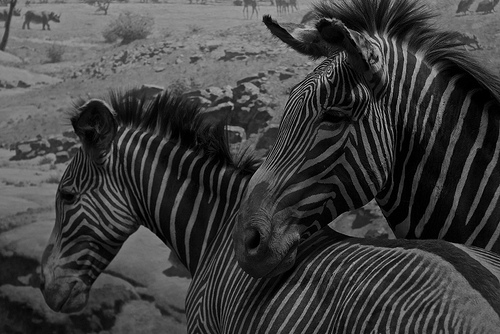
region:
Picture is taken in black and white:
[4, 8, 483, 324]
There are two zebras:
[44, 13, 492, 330]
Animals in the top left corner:
[1, 0, 71, 34]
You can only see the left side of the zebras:
[27, 9, 491, 328]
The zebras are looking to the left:
[37, 68, 385, 290]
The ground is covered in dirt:
[3, 47, 68, 223]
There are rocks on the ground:
[185, 19, 278, 136]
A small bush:
[94, 1, 155, 41]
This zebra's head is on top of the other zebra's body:
[211, 20, 470, 268]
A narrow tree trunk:
[2, 4, 18, 51]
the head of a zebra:
[201, 45, 453, 280]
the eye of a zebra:
[313, 94, 360, 154]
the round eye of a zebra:
[296, 88, 371, 160]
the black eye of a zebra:
[304, 96, 374, 135]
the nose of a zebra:
[222, 170, 315, 295]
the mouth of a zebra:
[246, 212, 323, 297]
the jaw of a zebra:
[313, 126, 398, 233]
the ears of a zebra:
[270, 7, 429, 105]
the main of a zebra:
[102, 96, 258, 188]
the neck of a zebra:
[114, 148, 269, 298]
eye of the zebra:
[297, 92, 364, 148]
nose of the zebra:
[189, 200, 301, 290]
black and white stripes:
[304, 131, 384, 188]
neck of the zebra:
[373, 100, 496, 217]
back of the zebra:
[120, 83, 253, 169]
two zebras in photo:
[0, 14, 475, 294]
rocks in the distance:
[108, 36, 199, 84]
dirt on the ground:
[130, 22, 232, 87]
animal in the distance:
[13, 4, 74, 39]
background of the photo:
[163, 6, 250, 42]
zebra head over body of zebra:
[176, 22, 397, 327]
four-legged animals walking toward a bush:
[0, 1, 155, 61]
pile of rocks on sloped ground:
[11, 30, 197, 82]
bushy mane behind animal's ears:
[262, 0, 477, 97]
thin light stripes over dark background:
[301, 241, 441, 327]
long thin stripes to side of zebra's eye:
[260, 76, 345, 181]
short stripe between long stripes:
[150, 145, 225, 265]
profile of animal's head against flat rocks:
[5, 92, 181, 322]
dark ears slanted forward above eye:
[251, 7, 391, 132]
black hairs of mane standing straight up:
[105, 81, 247, 172]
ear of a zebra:
[66, 99, 123, 164]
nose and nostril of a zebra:
[236, 201, 296, 277]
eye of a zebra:
[314, 98, 366, 130]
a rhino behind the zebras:
[15, 8, 69, 30]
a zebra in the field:
[34, 96, 498, 332]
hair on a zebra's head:
[304, 1, 479, 79]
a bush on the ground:
[107, 6, 158, 47]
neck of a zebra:
[122, 124, 299, 279]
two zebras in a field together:
[42, 10, 493, 332]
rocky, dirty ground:
[6, 6, 469, 331]